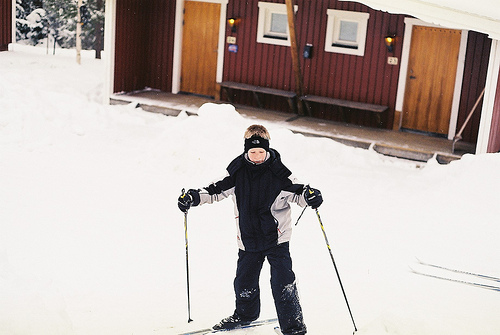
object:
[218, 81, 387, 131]
two benches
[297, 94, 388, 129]
bench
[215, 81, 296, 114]
bench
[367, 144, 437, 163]
stairs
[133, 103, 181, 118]
step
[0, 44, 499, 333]
snow field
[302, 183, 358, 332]
ski poles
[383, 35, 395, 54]
light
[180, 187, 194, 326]
ski pole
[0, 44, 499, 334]
ground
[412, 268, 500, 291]
ski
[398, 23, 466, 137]
door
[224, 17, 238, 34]
light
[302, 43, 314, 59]
mailbox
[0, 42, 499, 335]
snow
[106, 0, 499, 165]
building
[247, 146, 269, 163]
ski mask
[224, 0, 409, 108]
siding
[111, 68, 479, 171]
porch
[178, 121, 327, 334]
boy